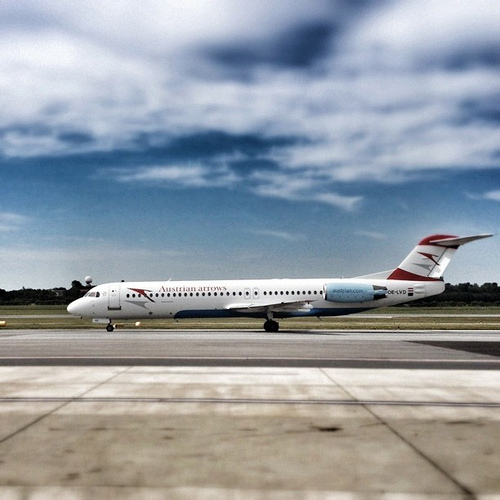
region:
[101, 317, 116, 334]
the nose wheel of a jet airplane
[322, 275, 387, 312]
a jet engine on an airplane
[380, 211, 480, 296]
the tail of an airplane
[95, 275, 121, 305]
a closed airplane door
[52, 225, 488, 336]
a white jet airplane on the taxiway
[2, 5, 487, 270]
a cloudy blue sky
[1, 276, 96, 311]
trees beyond the runway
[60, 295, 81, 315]
the nose of an airplane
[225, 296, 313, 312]
a wing on an airplane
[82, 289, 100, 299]
the cockpit windows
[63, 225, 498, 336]
large white airplane with red stripes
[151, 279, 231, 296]
Australian Arrows airplane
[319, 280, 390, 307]
propeller on an airplane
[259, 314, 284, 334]
landing wheels on an airplane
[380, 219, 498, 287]
red and white tail fin on an airplane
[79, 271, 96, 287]
white water tower in the distance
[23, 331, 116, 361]
airplane tarmac with white stripes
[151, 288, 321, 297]
line of airplane windows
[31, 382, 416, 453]
cement squares next to a tarmac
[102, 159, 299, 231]
blue skies with white clouds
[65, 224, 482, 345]
plane on airport tarmac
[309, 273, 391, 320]
jet engine on plane body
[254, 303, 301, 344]
wheel of landing gear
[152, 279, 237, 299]
name of airline on body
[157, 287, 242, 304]
windows on side for passengers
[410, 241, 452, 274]
logo on tail of plane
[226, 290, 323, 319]
wing on side of plane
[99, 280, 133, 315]
door on side near cockpit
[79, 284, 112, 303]
windows on front of cockpit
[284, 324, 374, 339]
shadow of plane on tarmac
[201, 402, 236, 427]
edge of a run way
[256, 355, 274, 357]
section of a road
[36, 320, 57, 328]
edge of the road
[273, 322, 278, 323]
back wheel of a plane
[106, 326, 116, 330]
front wheel of a plane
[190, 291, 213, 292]
windows of a plane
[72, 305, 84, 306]
front part of a plane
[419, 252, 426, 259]
back of a plane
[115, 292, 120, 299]
door of a plane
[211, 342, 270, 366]
part of a run way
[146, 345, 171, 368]
section of a run way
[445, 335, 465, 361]
edge of a run way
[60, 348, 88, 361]
side of the run way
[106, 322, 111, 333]
wheel of a plane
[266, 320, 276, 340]
back wheel of a plane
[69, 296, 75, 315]
front tip of a plane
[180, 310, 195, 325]
bottom of a plane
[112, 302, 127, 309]
door of a plane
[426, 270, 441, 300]
back part of a plane